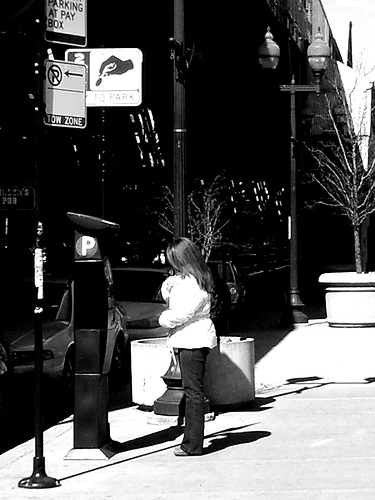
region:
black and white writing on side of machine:
[69, 234, 103, 262]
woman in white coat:
[158, 228, 224, 353]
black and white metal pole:
[32, 319, 46, 454]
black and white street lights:
[248, 30, 331, 75]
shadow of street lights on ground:
[266, 352, 373, 420]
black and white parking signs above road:
[31, 0, 151, 130]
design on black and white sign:
[91, 53, 137, 87]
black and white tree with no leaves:
[319, 77, 373, 261]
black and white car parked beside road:
[109, 261, 160, 337]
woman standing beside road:
[141, 228, 233, 470]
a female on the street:
[135, 236, 233, 470]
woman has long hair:
[144, 237, 228, 468]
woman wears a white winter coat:
[143, 235, 234, 475]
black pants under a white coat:
[156, 271, 224, 455]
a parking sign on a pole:
[65, 221, 107, 278]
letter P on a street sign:
[71, 231, 105, 269]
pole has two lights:
[249, 19, 334, 327]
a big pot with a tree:
[306, 81, 373, 330]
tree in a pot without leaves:
[306, 67, 368, 274]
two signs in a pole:
[25, 7, 91, 147]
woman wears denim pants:
[178, 347, 208, 449]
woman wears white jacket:
[163, 268, 212, 347]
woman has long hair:
[168, 236, 214, 289]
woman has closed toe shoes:
[172, 448, 185, 453]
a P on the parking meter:
[69, 210, 118, 452]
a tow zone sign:
[41, 63, 87, 125]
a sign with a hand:
[65, 50, 143, 104]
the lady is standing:
[163, 245, 218, 454]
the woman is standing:
[164, 237, 215, 456]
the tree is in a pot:
[318, 68, 374, 325]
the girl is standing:
[147, 201, 245, 465]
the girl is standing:
[132, 225, 213, 413]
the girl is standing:
[156, 260, 226, 435]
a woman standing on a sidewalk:
[158, 235, 216, 455]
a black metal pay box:
[64, 208, 121, 458]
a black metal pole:
[18, 128, 56, 483]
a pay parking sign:
[62, 45, 138, 106]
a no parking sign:
[40, 60, 85, 124]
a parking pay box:
[65, 206, 122, 461]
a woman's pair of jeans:
[172, 346, 209, 454]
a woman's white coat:
[158, 271, 219, 348]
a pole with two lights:
[256, 28, 328, 323]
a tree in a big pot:
[298, 65, 373, 327]